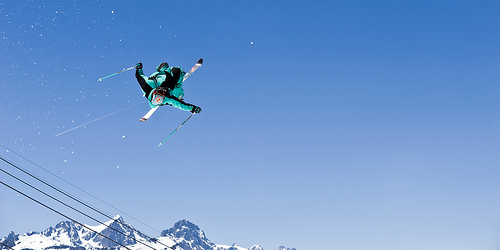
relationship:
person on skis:
[130, 56, 203, 113] [137, 55, 209, 123]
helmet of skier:
[144, 87, 169, 114] [134, 60, 202, 126]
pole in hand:
[155, 110, 193, 149] [189, 102, 201, 114]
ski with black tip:
[176, 55, 203, 85] [195, 55, 205, 65]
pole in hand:
[96, 55, 216, 127] [132, 59, 146, 74]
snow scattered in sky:
[49, 5, 163, 58] [2, 3, 494, 248]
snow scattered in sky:
[241, 32, 262, 51] [2, 3, 494, 248]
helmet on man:
[129, 86, 168, 108] [107, 44, 202, 153]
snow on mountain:
[27, 235, 42, 247] [11, 217, 200, 247]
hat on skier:
[148, 91, 163, 106] [124, 58, 223, 127]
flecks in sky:
[96, 68, 106, 87] [214, 9, 495, 246]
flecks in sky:
[59, 147, 85, 173] [214, 9, 495, 246]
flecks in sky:
[11, 9, 44, 49] [214, 9, 495, 246]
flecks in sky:
[8, 116, 38, 144] [214, 9, 495, 246]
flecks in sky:
[115, 135, 138, 171] [214, 9, 495, 246]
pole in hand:
[155, 112, 197, 148] [191, 102, 200, 116]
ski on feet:
[182, 58, 204, 84] [154, 57, 189, 84]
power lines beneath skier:
[2, 157, 162, 249] [105, 52, 200, 123]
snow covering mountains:
[27, 235, 42, 247] [31, 182, 200, 248]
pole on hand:
[96, 63, 141, 82] [134, 62, 143, 69]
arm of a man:
[131, 58, 149, 96] [124, 60, 201, 111]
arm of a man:
[135, 68, 149, 94] [132, 60, 202, 112]